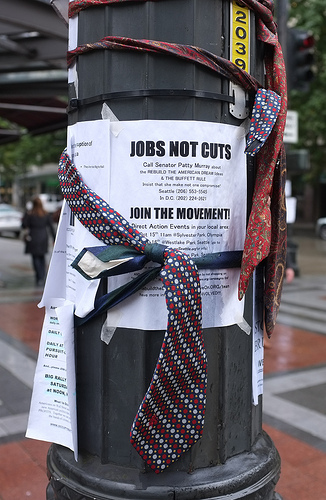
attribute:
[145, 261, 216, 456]
tie — red and white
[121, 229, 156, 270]
tie — knotted 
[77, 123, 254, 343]
notice — white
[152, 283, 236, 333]
dots — red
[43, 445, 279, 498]
base — large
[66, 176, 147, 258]
tie — red and white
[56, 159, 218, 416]
tie — red and white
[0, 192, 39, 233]
car — white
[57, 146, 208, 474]
tie — red and white, red and black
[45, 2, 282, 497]
pole — black, red, white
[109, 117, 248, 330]
paper — white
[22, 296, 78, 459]
paper — white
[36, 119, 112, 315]
paper — white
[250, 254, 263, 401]
paper — white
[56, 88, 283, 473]
tie — red and white, multicolor, red, white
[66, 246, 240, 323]
cloth — black